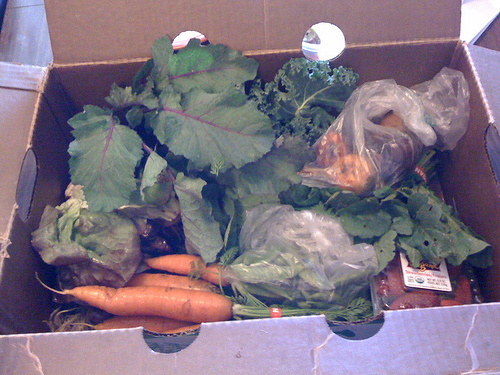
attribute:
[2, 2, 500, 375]
cardboard — box, wax coated, brown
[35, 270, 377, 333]
carrot — orange, fresh, whole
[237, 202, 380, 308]
bag — plastic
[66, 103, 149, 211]
leaf — green, fresh, healthy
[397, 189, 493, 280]
leaf — ruffled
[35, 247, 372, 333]
carrots — group, orange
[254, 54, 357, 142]
lettuce — bushy, green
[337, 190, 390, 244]
kale — green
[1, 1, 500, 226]
table — wood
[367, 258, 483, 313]
container — plastic